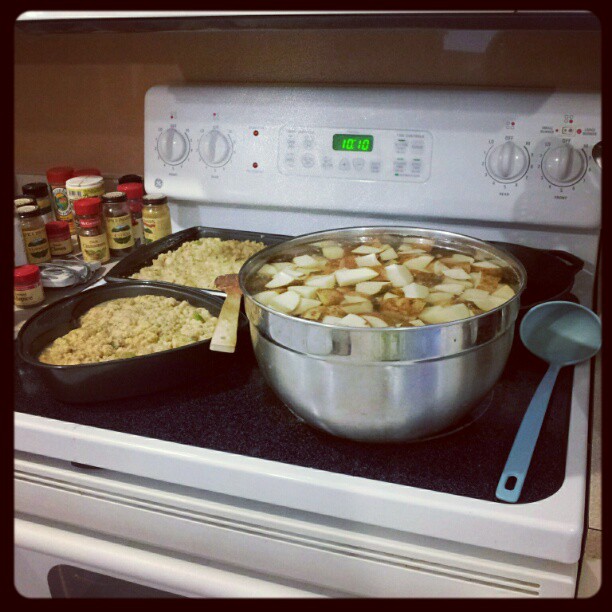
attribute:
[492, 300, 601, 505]
ladle — plastic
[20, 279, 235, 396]
pan — heart shaped